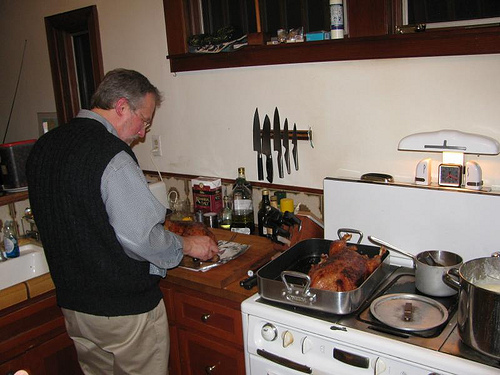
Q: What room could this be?
A: It is a kitchen.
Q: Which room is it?
A: It is a kitchen.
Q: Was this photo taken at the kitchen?
A: Yes, it was taken in the kitchen.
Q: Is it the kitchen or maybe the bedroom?
A: It is the kitchen.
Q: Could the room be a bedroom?
A: No, it is a kitchen.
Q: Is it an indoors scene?
A: Yes, it is indoors.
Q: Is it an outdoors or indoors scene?
A: It is indoors.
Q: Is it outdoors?
A: No, it is indoors.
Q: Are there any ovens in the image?
A: Yes, there is an oven.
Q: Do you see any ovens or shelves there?
A: Yes, there is an oven.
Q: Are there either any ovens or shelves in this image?
A: Yes, there is an oven.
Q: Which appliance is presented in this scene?
A: The appliance is an oven.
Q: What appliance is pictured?
A: The appliance is an oven.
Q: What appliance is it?
A: The appliance is an oven.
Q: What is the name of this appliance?
A: This is an oven.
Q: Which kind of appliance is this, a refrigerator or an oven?
A: This is an oven.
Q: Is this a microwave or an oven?
A: This is an oven.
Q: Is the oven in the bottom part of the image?
A: Yes, the oven is in the bottom of the image.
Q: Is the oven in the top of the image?
A: No, the oven is in the bottom of the image.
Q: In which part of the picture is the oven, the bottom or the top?
A: The oven is in the bottom of the image.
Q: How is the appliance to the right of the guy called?
A: The appliance is an oven.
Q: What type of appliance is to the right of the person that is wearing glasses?
A: The appliance is an oven.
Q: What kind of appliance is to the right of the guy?
A: The appliance is an oven.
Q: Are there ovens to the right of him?
A: Yes, there is an oven to the right of the guy.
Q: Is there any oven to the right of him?
A: Yes, there is an oven to the right of the guy.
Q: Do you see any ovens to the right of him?
A: Yes, there is an oven to the right of the guy.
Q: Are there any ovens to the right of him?
A: Yes, there is an oven to the right of the guy.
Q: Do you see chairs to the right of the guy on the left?
A: No, there is an oven to the right of the guy.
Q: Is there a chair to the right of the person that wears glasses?
A: No, there is an oven to the right of the guy.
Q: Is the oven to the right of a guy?
A: Yes, the oven is to the right of a guy.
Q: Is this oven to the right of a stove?
A: No, the oven is to the right of a guy.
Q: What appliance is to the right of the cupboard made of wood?
A: The appliance is an oven.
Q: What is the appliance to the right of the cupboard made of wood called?
A: The appliance is an oven.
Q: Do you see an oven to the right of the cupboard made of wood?
A: Yes, there is an oven to the right of the cupboard.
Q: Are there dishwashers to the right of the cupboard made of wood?
A: No, there is an oven to the right of the cupboard.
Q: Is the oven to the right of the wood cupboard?
A: Yes, the oven is to the right of the cupboard.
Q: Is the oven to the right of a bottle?
A: No, the oven is to the right of the cupboard.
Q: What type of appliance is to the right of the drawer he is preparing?
A: The appliance is an oven.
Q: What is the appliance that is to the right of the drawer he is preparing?
A: The appliance is an oven.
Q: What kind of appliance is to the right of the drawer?
A: The appliance is an oven.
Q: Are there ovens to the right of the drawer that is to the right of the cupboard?
A: Yes, there is an oven to the right of the drawer.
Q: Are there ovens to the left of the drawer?
A: No, the oven is to the right of the drawer.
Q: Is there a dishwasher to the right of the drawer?
A: No, there is an oven to the right of the drawer.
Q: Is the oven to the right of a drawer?
A: Yes, the oven is to the right of a drawer.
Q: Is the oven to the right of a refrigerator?
A: No, the oven is to the right of a drawer.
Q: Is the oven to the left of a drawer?
A: No, the oven is to the right of a drawer.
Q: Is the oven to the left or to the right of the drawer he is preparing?
A: The oven is to the right of the drawer.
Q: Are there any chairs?
A: No, there are no chairs.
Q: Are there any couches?
A: No, there are no couches.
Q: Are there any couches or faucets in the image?
A: No, there are no couches or faucets.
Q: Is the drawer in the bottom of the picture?
A: Yes, the drawer is in the bottom of the image.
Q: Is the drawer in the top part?
A: No, the drawer is in the bottom of the image.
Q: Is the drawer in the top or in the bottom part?
A: The drawer is in the bottom of the image.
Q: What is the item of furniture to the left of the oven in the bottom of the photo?
A: The piece of furniture is a drawer.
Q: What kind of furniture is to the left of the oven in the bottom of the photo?
A: The piece of furniture is a drawer.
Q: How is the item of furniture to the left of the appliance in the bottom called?
A: The piece of furniture is a drawer.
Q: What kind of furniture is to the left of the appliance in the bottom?
A: The piece of furniture is a drawer.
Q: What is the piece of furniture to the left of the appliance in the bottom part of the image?
A: The piece of furniture is a drawer.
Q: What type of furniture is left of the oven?
A: The piece of furniture is a drawer.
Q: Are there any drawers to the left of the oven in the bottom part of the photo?
A: Yes, there is a drawer to the left of the oven.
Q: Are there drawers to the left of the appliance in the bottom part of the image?
A: Yes, there is a drawer to the left of the oven.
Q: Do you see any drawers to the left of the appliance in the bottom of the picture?
A: Yes, there is a drawer to the left of the oven.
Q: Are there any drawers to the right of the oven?
A: No, the drawer is to the left of the oven.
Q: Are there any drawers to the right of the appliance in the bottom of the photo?
A: No, the drawer is to the left of the oven.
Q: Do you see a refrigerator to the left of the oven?
A: No, there is a drawer to the left of the oven.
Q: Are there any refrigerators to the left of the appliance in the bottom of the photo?
A: No, there is a drawer to the left of the oven.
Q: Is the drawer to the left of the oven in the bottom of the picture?
A: Yes, the drawer is to the left of the oven.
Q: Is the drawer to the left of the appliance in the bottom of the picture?
A: Yes, the drawer is to the left of the oven.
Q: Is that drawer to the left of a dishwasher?
A: No, the drawer is to the left of the oven.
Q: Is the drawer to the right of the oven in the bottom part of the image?
A: No, the drawer is to the left of the oven.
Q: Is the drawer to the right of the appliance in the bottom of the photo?
A: No, the drawer is to the left of the oven.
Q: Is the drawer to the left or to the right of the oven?
A: The drawer is to the left of the oven.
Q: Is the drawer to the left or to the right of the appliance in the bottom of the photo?
A: The drawer is to the left of the oven.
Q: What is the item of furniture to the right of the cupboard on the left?
A: The piece of furniture is a drawer.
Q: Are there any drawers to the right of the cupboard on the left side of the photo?
A: Yes, there is a drawer to the right of the cupboard.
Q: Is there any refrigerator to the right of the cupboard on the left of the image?
A: No, there is a drawer to the right of the cupboard.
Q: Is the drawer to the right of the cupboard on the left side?
A: Yes, the drawer is to the right of the cupboard.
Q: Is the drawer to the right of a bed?
A: No, the drawer is to the right of the cupboard.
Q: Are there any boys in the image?
A: No, there are no boys.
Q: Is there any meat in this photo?
A: Yes, there is meat.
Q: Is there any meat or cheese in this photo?
A: Yes, there is meat.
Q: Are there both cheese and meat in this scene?
A: No, there is meat but no cheese.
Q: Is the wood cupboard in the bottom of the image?
A: Yes, the cupboard is in the bottom of the image.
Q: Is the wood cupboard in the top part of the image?
A: No, the cupboard is in the bottom of the image.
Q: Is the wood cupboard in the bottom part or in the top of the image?
A: The cupboard is in the bottom of the image.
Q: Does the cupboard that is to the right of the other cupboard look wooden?
A: Yes, the cupboard is wooden.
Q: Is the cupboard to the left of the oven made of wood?
A: Yes, the cupboard is made of wood.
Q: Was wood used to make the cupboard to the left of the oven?
A: Yes, the cupboard is made of wood.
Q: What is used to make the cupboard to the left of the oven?
A: The cupboard is made of wood.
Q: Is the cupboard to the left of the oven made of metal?
A: No, the cupboard is made of wood.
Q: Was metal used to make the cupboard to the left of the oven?
A: No, the cupboard is made of wood.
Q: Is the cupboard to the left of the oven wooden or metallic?
A: The cupboard is wooden.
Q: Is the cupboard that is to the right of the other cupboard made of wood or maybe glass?
A: The cupboard is made of wood.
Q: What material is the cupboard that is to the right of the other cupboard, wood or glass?
A: The cupboard is made of wood.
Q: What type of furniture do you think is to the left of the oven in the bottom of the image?
A: The piece of furniture is a cupboard.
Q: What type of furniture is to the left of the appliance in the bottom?
A: The piece of furniture is a cupboard.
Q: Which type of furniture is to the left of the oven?
A: The piece of furniture is a cupboard.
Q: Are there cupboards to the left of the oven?
A: Yes, there is a cupboard to the left of the oven.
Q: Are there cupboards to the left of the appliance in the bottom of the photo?
A: Yes, there is a cupboard to the left of the oven.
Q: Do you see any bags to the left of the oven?
A: No, there is a cupboard to the left of the oven.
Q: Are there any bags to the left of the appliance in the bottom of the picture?
A: No, there is a cupboard to the left of the oven.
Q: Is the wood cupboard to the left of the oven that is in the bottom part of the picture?
A: Yes, the cupboard is to the left of the oven.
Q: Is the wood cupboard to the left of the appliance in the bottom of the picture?
A: Yes, the cupboard is to the left of the oven.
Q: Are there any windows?
A: Yes, there are windows.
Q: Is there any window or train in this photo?
A: Yes, there are windows.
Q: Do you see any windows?
A: Yes, there are windows.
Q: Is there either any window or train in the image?
A: Yes, there are windows.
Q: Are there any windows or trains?
A: Yes, there are windows.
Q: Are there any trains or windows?
A: Yes, there are windows.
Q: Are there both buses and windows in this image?
A: No, there are windows but no buses.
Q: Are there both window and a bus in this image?
A: No, there are windows but no buses.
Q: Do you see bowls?
A: No, there are no bowls.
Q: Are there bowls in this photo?
A: No, there are no bowls.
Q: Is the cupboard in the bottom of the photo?
A: Yes, the cupboard is in the bottom of the image.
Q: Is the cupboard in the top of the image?
A: No, the cupboard is in the bottom of the image.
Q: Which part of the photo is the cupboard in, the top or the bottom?
A: The cupboard is in the bottom of the image.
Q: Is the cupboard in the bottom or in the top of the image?
A: The cupboard is in the bottom of the image.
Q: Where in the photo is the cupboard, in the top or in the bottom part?
A: The cupboard is in the bottom of the image.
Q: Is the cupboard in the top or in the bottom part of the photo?
A: The cupboard is in the bottom of the image.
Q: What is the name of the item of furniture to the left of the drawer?
A: The piece of furniture is a cupboard.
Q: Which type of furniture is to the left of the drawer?
A: The piece of furniture is a cupboard.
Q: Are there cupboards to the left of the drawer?
A: Yes, there is a cupboard to the left of the drawer.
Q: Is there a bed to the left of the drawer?
A: No, there is a cupboard to the left of the drawer.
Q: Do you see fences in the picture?
A: No, there are no fences.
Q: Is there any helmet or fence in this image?
A: No, there are no fences or helmets.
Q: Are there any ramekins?
A: No, there are no ramekins.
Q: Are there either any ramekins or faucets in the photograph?
A: No, there are no ramekins or faucets.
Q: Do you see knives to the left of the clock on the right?
A: Yes, there are knives to the left of the clock.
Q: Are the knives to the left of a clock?
A: Yes, the knives are to the left of a clock.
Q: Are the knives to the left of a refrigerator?
A: No, the knives are to the left of a clock.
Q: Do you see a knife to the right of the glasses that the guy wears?
A: Yes, there are knives to the right of the glasses.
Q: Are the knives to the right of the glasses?
A: Yes, the knives are to the right of the glasses.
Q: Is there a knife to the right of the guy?
A: Yes, there are knives to the right of the guy.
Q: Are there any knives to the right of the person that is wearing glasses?
A: Yes, there are knives to the right of the guy.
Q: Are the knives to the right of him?
A: Yes, the knives are to the right of a guy.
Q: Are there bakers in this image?
A: No, there are no bakers.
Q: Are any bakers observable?
A: No, there are no bakers.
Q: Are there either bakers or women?
A: No, there are no bakers or women.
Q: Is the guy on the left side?
A: Yes, the guy is on the left of the image.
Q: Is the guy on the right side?
A: No, the guy is on the left of the image.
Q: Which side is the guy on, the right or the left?
A: The guy is on the left of the image.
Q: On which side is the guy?
A: The guy is on the left of the image.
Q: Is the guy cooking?
A: Yes, the guy is cooking.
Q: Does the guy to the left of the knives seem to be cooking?
A: Yes, the guy is cooking.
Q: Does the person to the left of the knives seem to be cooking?
A: Yes, the guy is cooking.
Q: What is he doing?
A: The guy is cooking.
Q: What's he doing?
A: The guy is cooking.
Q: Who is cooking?
A: The guy is cooking.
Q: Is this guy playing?
A: No, the guy is cooking.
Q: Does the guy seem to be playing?
A: No, the guy is cooking.